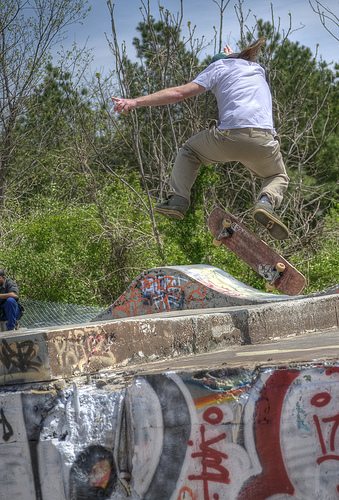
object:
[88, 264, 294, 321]
ramp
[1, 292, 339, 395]
ground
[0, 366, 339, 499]
graffitti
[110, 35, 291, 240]
man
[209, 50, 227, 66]
cap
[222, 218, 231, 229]
wheel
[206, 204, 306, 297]
skateboard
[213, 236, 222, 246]
wheel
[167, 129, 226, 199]
leg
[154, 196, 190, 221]
foot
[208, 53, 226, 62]
head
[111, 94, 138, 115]
hand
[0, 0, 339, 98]
air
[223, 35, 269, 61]
brown hair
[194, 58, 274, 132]
grey shirt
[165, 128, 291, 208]
tan pants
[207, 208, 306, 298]
skateboard flips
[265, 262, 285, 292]
tan wheels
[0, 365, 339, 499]
graffiti on wall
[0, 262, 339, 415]
ramp is behind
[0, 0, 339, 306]
green trees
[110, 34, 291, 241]
jumping off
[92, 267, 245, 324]
graffiti on the wall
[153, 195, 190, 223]
shoe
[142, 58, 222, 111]
arm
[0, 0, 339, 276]
trees and branches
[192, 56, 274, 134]
purple shirt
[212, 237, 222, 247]
wheel on a skate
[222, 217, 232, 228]
wheel on a skate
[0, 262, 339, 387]
concrete ramp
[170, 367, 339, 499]
red letter painted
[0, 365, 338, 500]
spray paint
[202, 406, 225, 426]
letter painted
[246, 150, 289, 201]
he leg of a man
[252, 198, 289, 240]
foot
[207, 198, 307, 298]
skateboard in mid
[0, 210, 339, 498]
above rink.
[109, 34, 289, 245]
in mid air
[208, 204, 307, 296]
mid air above rink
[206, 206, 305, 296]
skateboard above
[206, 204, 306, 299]
skateboardon air